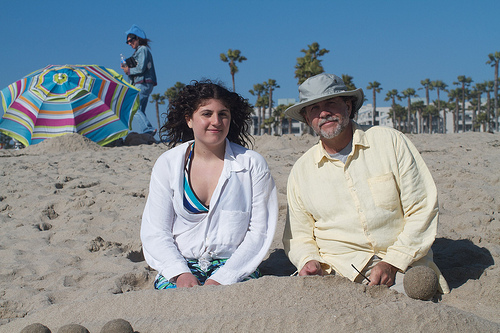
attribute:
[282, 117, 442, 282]
shirt — yellow, white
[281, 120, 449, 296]
shirt — yellow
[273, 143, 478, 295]
shirt — yellow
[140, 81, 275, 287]
woman — smiling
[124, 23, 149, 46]
hat — blue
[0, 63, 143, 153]
umbrella — striped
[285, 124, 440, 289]
shirt — yellow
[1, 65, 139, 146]
umbrella — open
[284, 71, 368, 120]
hat — gray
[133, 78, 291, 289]
woman — white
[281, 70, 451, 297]
man — yellow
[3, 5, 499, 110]
sky — blue, clear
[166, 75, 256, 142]
hair — brown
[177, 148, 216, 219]
top — blue, white, striped